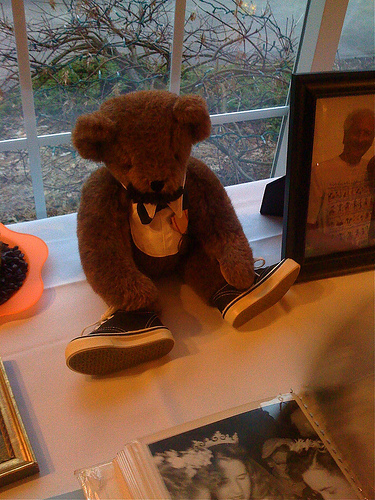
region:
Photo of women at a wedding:
[155, 422, 351, 498]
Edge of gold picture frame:
[2, 358, 36, 487]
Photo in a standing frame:
[261, 70, 371, 282]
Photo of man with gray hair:
[339, 108, 373, 158]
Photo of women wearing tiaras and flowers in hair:
[153, 426, 330, 495]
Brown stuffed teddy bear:
[62, 92, 289, 369]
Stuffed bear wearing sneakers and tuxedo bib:
[64, 91, 279, 372]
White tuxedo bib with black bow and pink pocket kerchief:
[128, 195, 193, 260]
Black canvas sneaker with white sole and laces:
[65, 305, 167, 380]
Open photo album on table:
[68, 426, 347, 497]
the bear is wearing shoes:
[204, 270, 290, 310]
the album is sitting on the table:
[229, 379, 321, 444]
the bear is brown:
[90, 199, 115, 249]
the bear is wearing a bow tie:
[134, 195, 189, 216]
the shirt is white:
[323, 170, 348, 183]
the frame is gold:
[13, 424, 27, 476]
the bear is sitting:
[67, 222, 143, 301]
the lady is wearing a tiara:
[197, 429, 243, 467]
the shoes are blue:
[109, 312, 155, 339]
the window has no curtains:
[185, 17, 294, 130]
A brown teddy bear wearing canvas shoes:
[65, 91, 299, 374]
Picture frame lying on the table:
[73, 391, 373, 498]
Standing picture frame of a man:
[260, 72, 373, 283]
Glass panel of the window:
[0, 0, 373, 222]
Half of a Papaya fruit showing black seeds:
[0, 224, 47, 316]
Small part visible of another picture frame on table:
[1, 361, 40, 486]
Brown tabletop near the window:
[1, 269, 373, 498]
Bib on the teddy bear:
[131, 198, 188, 255]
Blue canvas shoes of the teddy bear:
[63, 257, 301, 374]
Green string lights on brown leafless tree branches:
[1, 1, 293, 157]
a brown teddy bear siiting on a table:
[57, 104, 263, 338]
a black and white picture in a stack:
[79, 402, 374, 498]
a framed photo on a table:
[275, 59, 372, 316]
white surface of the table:
[156, 337, 268, 392]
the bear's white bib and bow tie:
[119, 185, 202, 260]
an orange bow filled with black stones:
[1, 227, 57, 324]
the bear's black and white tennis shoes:
[68, 257, 302, 375]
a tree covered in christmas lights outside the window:
[30, 6, 284, 93]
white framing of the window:
[0, 17, 61, 175]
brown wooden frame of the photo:
[291, 94, 302, 241]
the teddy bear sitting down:
[64, 91, 299, 374]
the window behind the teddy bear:
[0, 0, 373, 226]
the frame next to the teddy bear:
[259, 69, 373, 285]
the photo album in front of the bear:
[72, 294, 373, 498]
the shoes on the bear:
[64, 257, 299, 375]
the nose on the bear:
[149, 178, 165, 190]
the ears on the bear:
[71, 93, 211, 160]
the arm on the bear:
[76, 166, 162, 312]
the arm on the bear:
[187, 153, 253, 290]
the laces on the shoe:
[79, 303, 120, 336]